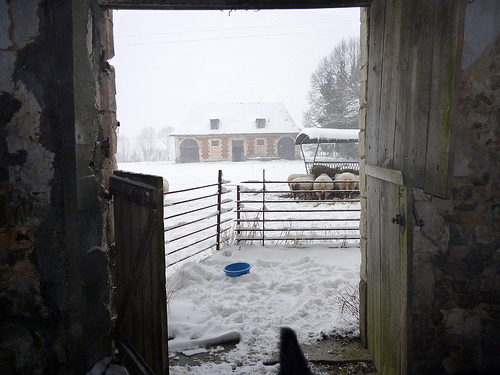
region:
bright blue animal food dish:
[223, 260, 255, 276]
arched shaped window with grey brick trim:
[175, 135, 204, 164]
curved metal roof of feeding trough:
[292, 125, 364, 145]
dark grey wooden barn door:
[102, 170, 172, 371]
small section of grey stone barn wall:
[411, 196, 498, 372]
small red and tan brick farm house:
[169, 99, 303, 164]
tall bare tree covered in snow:
[137, 123, 158, 162]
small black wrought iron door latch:
[388, 210, 408, 230]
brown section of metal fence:
[233, 168, 368, 250]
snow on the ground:
[268, 284, 311, 323]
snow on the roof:
[194, 97, 297, 133]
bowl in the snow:
[221, 255, 248, 277]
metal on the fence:
[220, 191, 340, 243]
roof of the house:
[184, 88, 294, 141]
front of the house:
[170, 139, 287, 164]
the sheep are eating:
[291, 171, 356, 198]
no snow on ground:
[329, 344, 363, 370]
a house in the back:
[163, 110, 291, 170]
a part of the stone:
[267, 313, 302, 364]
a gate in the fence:
[222, 171, 364, 243]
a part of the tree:
[297, 50, 377, 145]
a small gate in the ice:
[201, 159, 273, 249]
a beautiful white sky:
[139, 33, 309, 104]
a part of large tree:
[300, 30, 375, 160]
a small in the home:
[341, 109, 440, 374]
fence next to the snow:
[218, 142, 325, 246]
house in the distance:
[167, 94, 298, 176]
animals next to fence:
[275, 161, 364, 211]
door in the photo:
[328, 9, 488, 348]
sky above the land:
[166, 23, 283, 77]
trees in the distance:
[136, 115, 184, 160]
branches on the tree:
[306, 57, 347, 124]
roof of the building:
[196, 92, 276, 136]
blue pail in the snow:
[222, 255, 253, 281]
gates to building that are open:
[126, 161, 420, 365]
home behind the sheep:
[163, 95, 305, 169]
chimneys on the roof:
[208, 114, 274, 132]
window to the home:
[208, 138, 224, 148]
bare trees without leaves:
[134, 118, 175, 163]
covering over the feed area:
[294, 114, 355, 153]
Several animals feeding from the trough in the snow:
[277, 157, 386, 219]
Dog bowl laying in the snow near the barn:
[217, 248, 260, 293]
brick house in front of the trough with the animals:
[157, 73, 318, 172]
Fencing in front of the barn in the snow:
[163, 163, 359, 284]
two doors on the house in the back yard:
[168, 130, 304, 165]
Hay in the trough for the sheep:
[302, 155, 360, 186]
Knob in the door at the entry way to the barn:
[380, 208, 430, 232]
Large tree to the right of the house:
[285, 23, 359, 177]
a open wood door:
[365, 35, 452, 374]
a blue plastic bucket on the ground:
[222, 261, 248, 278]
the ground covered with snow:
[169, 155, 263, 202]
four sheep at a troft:
[282, 170, 364, 198]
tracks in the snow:
[257, 256, 340, 335]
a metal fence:
[230, 175, 356, 250]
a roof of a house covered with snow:
[168, 104, 308, 152]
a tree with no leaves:
[315, 40, 356, 115]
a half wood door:
[102, 168, 176, 372]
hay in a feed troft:
[305, 157, 356, 177]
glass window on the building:
[255, 135, 263, 145]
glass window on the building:
[230, 137, 240, 147]